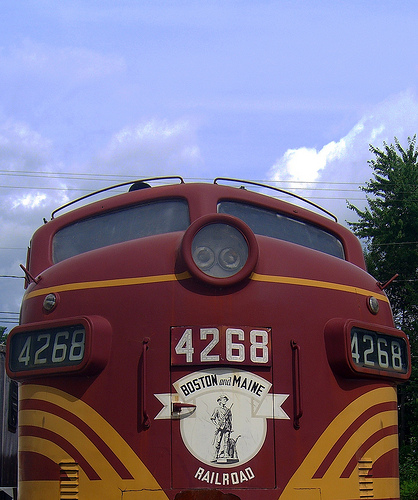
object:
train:
[0, 166, 412, 500]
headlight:
[179, 211, 260, 293]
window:
[47, 191, 192, 264]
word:
[187, 465, 255, 490]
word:
[179, 369, 218, 397]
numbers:
[171, 327, 196, 367]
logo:
[147, 367, 293, 487]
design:
[277, 389, 398, 498]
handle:
[378, 269, 399, 291]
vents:
[357, 475, 370, 482]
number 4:
[14, 334, 33, 370]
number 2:
[34, 332, 50, 365]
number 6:
[51, 328, 69, 366]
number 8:
[65, 326, 88, 367]